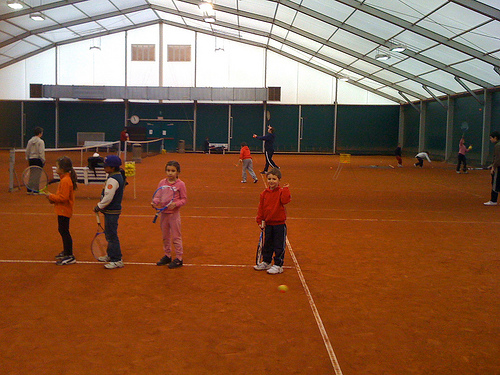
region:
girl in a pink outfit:
[151, 158, 196, 270]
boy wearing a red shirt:
[247, 163, 296, 228]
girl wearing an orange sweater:
[41, 159, 84, 219]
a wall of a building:
[309, 102, 349, 148]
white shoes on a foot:
[261, 265, 287, 275]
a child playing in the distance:
[386, 142, 417, 169]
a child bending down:
[407, 141, 437, 170]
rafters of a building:
[302, 14, 342, 47]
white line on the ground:
[299, 280, 342, 350]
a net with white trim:
[110, 130, 175, 162]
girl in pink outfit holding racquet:
[144, 157, 191, 272]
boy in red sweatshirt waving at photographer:
[249, 166, 298, 281]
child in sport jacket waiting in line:
[88, 148, 128, 273]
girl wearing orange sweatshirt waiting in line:
[39, 151, 84, 275]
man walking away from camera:
[20, 121, 52, 199]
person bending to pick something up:
[412, 146, 434, 173]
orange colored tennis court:
[7, 275, 316, 373]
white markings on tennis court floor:
[0, 247, 363, 372]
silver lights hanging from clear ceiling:
[366, 40, 417, 60]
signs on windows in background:
[127, 41, 195, 63]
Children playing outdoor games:
[5, 98, 352, 291]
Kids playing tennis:
[10, 155, 301, 281]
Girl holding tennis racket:
[146, 155, 189, 276]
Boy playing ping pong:
[2, 106, 48, 196]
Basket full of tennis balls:
[123, 155, 148, 196]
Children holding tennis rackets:
[16, 145, 209, 283]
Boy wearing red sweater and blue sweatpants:
[253, 165, 293, 270]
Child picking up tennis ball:
[411, 143, 442, 191]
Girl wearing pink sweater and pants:
[146, 155, 198, 271]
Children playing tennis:
[224, 113, 286, 183]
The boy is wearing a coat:
[252, 172, 293, 229]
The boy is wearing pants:
[246, 210, 289, 296]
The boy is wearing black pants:
[260, 156, 315, 221]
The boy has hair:
[257, 157, 277, 172]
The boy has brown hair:
[262, 156, 288, 182]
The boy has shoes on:
[254, 261, 307, 308]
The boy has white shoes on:
[236, 253, 315, 306]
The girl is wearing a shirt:
[150, 173, 195, 213]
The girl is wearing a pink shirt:
[144, 170, 197, 212]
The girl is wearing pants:
[150, 205, 188, 287]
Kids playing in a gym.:
[5, 142, 387, 294]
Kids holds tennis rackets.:
[24, 151, 297, 287]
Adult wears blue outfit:
[246, 118, 290, 178]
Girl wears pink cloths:
[148, 153, 200, 275]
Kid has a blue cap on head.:
[85, 148, 140, 276]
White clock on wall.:
[126, 113, 142, 128]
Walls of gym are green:
[3, 96, 497, 155]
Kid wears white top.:
[409, 144, 434, 172]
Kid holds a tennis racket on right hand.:
[245, 162, 307, 281]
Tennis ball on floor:
[275, 278, 294, 298]